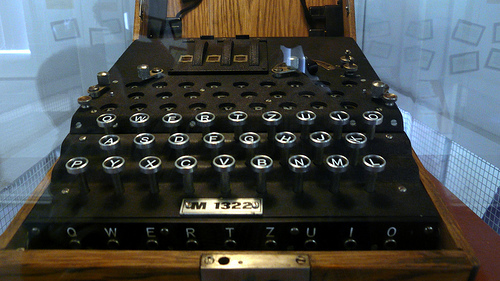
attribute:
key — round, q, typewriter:
[96, 107, 120, 128]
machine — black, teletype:
[23, 0, 446, 253]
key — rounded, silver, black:
[247, 149, 276, 176]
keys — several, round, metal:
[61, 149, 391, 172]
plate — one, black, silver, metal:
[179, 190, 267, 220]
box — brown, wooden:
[11, 17, 468, 262]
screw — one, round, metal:
[202, 252, 213, 267]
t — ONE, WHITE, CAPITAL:
[223, 222, 237, 240]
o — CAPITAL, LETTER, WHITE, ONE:
[381, 222, 401, 242]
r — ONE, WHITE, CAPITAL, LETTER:
[180, 220, 196, 242]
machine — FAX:
[3, 5, 480, 271]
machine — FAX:
[38, 30, 444, 241]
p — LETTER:
[65, 151, 92, 177]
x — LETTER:
[140, 149, 161, 175]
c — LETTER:
[170, 149, 198, 173]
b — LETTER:
[247, 150, 278, 172]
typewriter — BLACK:
[33, 30, 445, 236]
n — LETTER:
[288, 150, 318, 171]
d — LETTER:
[167, 125, 192, 147]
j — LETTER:
[306, 126, 333, 149]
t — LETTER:
[227, 103, 253, 123]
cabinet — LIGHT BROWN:
[135, 5, 352, 38]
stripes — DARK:
[145, 10, 344, 33]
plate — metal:
[199, 188, 262, 229]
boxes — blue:
[352, 23, 499, 130]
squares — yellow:
[154, 35, 277, 91]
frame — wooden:
[39, 52, 446, 279]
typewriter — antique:
[48, 28, 458, 249]